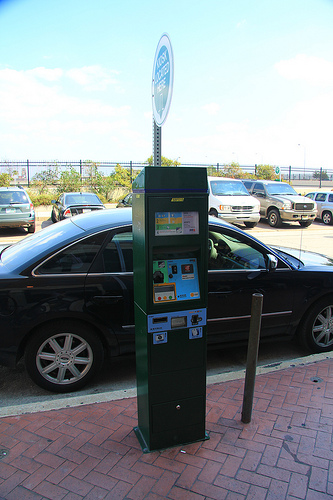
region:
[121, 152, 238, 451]
Machine for parking by road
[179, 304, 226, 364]
Slot to put in money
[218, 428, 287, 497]
Sidewalk is made of brick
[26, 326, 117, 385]
Wheel is black with chrome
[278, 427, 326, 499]
Stain on the pavement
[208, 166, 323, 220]
Cars parked in the lot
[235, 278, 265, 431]
Pole on side of road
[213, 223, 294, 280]
Side window on car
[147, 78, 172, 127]
Sign on top of metal pole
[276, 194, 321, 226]
Front end of suv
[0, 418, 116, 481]
red bricks on sidewalk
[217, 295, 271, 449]
thin silver pole on sidewalk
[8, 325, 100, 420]
black tire with silver rim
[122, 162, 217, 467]
tall kiosk of some sort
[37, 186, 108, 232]
black car parked in lo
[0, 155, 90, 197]
GREEN TREES AND BLACK GATE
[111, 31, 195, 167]
GREEN AND WHITE SIGN ON POST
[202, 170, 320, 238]
truck and van in lot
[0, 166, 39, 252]
a light green station wagon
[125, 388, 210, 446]
green box with silver lock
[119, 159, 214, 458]
green machine on sidewalk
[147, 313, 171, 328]
rectangle slot in machine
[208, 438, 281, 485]
red bricks on sidewalk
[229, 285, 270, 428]
metal pole in sidewalk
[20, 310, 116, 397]
wheel on parked car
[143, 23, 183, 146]
round sign on pole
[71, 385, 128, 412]
curb on side of street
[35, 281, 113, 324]
reflection on side of car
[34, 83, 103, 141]
cloud in daytime sky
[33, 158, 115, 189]
vegetation in front of fence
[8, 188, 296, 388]
car parked on street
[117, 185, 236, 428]
car meter box on brick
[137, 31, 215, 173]
street sign on street pole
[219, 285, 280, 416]
small metal pole on ground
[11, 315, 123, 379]
black tire wheel on car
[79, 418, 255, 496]
brick ground for terrain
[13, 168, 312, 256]
cars parke din lot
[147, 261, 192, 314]
credit card slots on machine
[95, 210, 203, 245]
different colors on machine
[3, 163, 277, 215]
metal fence by lot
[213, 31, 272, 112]
a sky is clear and white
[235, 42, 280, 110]
a sky is clear and white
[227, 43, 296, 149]
a sky is clear and white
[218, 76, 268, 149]
a sky is clear and white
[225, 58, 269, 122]
a sky is clear and white